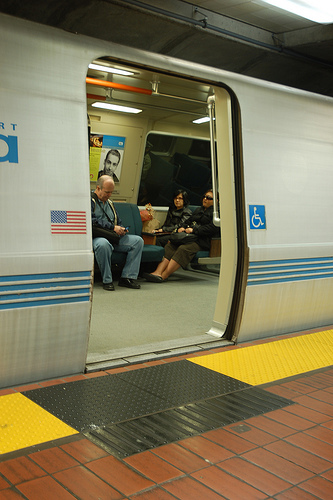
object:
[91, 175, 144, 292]
man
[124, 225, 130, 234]
phone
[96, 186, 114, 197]
spectacle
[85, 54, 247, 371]
door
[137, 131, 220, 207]
window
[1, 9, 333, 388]
train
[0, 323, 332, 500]
ground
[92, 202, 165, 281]
chair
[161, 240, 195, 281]
legs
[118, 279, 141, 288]
shoe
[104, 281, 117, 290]
shoe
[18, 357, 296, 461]
mat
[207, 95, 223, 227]
pole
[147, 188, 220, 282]
person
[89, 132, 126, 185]
poster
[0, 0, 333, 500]
background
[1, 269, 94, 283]
stripe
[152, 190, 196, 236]
woman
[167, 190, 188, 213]
hair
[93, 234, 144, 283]
jeans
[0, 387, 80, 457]
line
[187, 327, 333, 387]
line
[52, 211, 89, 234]
flag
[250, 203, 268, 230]
sign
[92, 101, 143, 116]
fixture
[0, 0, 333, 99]
ceiling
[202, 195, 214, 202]
sunglasses